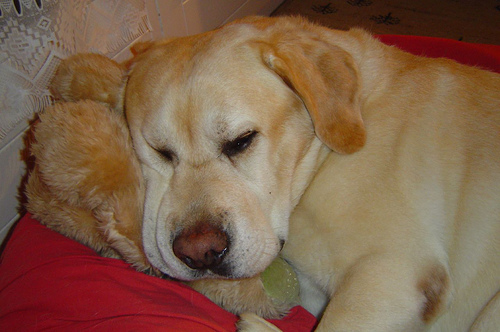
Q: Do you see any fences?
A: No, there are no fences.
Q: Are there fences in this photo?
A: No, there are no fences.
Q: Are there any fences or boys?
A: No, there are no fences or boys.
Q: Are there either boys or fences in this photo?
A: No, there are no fences or boys.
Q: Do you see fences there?
A: No, there are no fences.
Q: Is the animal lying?
A: Yes, the animal is lying.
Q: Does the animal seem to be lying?
A: Yes, the animal is lying.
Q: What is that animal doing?
A: The animal is lying.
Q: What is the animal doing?
A: The animal is lying.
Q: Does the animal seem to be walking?
A: No, the animal is lying.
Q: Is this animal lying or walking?
A: The animal is lying.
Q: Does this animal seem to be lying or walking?
A: The animal is lying.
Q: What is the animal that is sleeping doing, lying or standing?
A: The animal is lying.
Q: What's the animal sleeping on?
A: The animal is sleeping on the stuffed animal.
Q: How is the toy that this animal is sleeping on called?
A: The toy is a stuffed animal.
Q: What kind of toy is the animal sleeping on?
A: The animal is sleeping on the stuffed animal.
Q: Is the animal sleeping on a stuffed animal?
A: Yes, the animal is sleeping on a stuffed animal.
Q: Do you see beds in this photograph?
A: Yes, there is a bed.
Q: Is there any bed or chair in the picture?
A: Yes, there is a bed.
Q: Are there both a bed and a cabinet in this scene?
A: No, there is a bed but no cabinets.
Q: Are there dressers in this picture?
A: No, there are no dressers.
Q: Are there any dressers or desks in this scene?
A: No, there are no dressers or desks.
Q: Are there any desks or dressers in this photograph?
A: No, there are no dressers or desks.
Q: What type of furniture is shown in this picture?
A: The furniture is a bed.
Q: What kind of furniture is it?
A: The piece of furniture is a bed.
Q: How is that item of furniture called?
A: This is a bed.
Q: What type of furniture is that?
A: This is a bed.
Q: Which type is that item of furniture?
A: This is a bed.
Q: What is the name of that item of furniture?
A: This is a bed.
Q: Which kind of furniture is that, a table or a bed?
A: This is a bed.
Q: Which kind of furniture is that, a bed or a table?
A: This is a bed.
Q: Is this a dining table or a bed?
A: This is a bed.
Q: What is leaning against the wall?
A: The bed is leaning against the wall.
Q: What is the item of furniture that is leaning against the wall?
A: The piece of furniture is a bed.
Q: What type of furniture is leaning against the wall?
A: The piece of furniture is a bed.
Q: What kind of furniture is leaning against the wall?
A: The piece of furniture is a bed.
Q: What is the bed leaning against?
A: The bed is leaning against the wall.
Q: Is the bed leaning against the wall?
A: Yes, the bed is leaning against the wall.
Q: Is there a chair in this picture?
A: No, there are no chairs.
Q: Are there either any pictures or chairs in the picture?
A: No, there are no chairs or pictures.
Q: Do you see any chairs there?
A: No, there are no chairs.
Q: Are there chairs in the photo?
A: No, there are no chairs.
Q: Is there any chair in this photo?
A: No, there are no chairs.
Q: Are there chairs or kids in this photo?
A: No, there are no chairs or kids.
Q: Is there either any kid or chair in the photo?
A: No, there are no chairs or children.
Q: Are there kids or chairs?
A: No, there are no chairs or kids.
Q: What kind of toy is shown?
A: The toy is a stuffed animal.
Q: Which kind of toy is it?
A: The toy is a stuffed animal.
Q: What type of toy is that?
A: This is a stuffed animal.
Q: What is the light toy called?
A: The toy is a stuffed animal.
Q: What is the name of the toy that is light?
A: The toy is a stuffed animal.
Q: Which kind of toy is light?
A: The toy is a stuffed animal.